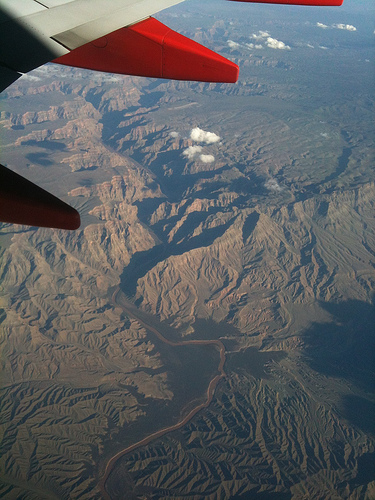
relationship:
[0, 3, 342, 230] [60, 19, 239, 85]
plane has an engine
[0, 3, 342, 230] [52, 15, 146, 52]
plane has a flap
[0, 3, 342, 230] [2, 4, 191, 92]
plane has a wing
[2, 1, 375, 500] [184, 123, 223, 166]
mountains are under a cloud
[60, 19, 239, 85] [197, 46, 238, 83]
engine has a tip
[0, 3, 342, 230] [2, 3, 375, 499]
plane in air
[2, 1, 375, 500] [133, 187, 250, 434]
mountains has a trail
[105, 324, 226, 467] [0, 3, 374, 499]
river on ground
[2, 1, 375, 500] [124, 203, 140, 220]
mountains has a peak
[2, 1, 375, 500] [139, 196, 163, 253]
mountains has a ridge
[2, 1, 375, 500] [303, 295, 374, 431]
mountains has a shadow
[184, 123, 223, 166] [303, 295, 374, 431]
cloud has a shadow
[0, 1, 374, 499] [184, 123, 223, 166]
sky has a cloud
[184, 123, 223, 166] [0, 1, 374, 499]
cloud in sky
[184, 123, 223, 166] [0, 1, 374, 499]
cloud floating in sky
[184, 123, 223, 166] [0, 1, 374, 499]
cloud hovering in sky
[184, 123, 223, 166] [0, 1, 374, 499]
cloud moving in sky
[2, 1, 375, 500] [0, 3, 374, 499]
mountains are on ground